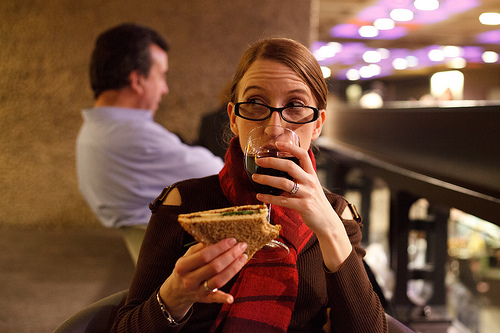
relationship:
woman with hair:
[115, 33, 385, 325] [224, 34, 326, 109]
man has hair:
[75, 20, 390, 308] [88, 20, 169, 97]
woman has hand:
[115, 33, 385, 325] [251, 139, 334, 232]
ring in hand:
[290, 182, 299, 194] [251, 139, 334, 232]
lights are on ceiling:
[356, 0, 447, 40] [312, 0, 494, 90]